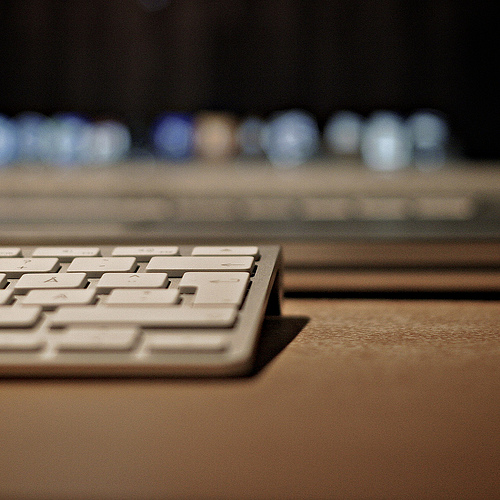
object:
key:
[142, 333, 230, 355]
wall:
[389, 155, 428, 197]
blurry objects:
[258, 109, 450, 176]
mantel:
[131, 146, 499, 250]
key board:
[0, 241, 288, 379]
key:
[145, 255, 255, 278]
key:
[190, 244, 261, 258]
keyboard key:
[16, 272, 87, 289]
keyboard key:
[32, 244, 101, 263]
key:
[0, 256, 61, 278]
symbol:
[126, 272, 142, 280]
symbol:
[16, 259, 32, 270]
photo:
[0, 0, 496, 492]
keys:
[1, 304, 237, 355]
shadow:
[244, 311, 314, 378]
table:
[0, 243, 497, 495]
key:
[54, 322, 143, 355]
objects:
[8, 111, 444, 173]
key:
[177, 271, 250, 309]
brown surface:
[108, 285, 283, 383]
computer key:
[97, 272, 169, 288]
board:
[0, 241, 289, 386]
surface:
[300, 284, 470, 430]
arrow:
[219, 261, 249, 267]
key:
[107, 287, 181, 306]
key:
[22, 288, 97, 311]